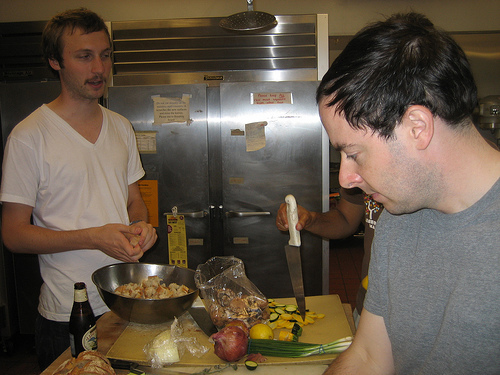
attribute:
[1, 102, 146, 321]
tshirt — white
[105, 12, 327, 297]
refrigerator — metal , commercial 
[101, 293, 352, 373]
chopping board — beige 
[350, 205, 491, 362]
shirt — gray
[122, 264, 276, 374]
item — vegetable 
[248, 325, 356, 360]
bunch — small 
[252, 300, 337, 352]
sliced vegetables — sliced 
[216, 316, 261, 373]
onions — bundle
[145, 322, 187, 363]
onion — white 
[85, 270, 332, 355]
counter — metal, silver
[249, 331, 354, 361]
onions — green 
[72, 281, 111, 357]
beer — open , bottle 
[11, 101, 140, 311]
shirt. — white 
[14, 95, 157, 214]
tshirt — white , v-necked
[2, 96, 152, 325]
shirt — white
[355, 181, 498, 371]
shirt — grey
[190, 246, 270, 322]
bag — plastic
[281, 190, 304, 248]
handle — white 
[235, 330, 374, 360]
green onions — small , green 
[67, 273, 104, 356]
bottle — brown 